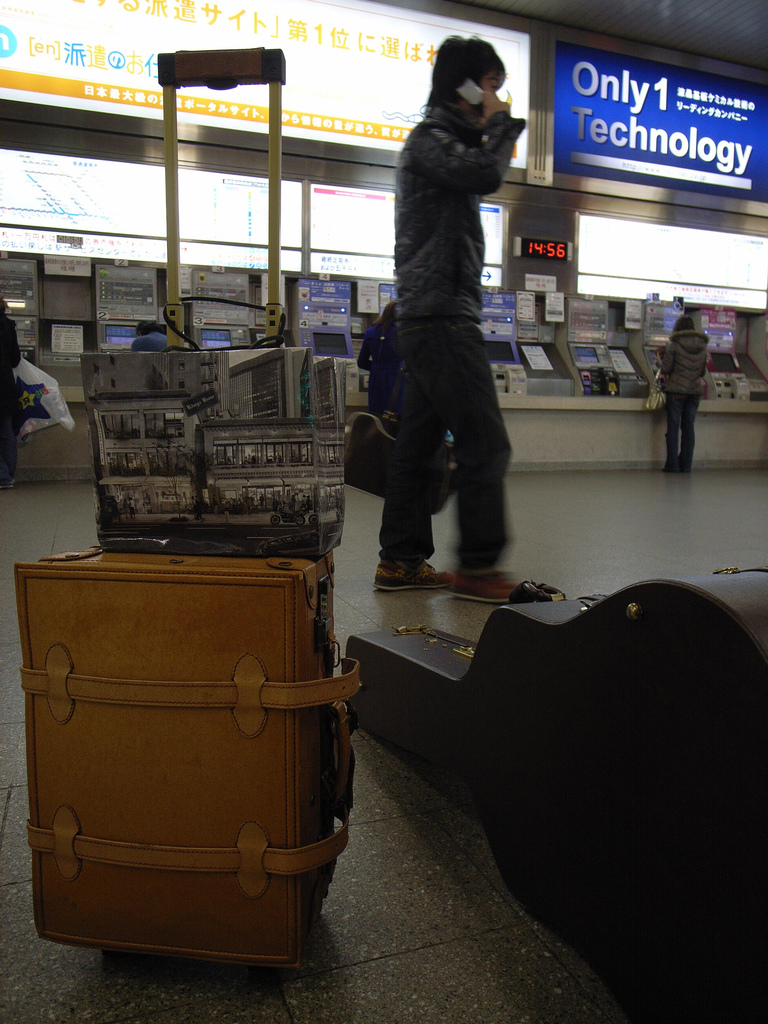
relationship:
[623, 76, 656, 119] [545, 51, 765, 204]
letter on sign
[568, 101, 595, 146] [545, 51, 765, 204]
letter on sign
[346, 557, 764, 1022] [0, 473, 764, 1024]
case on floor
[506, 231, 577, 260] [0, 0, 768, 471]
clock on wall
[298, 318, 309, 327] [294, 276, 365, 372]
number on kiosk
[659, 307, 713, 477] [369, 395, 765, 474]
person standing at counter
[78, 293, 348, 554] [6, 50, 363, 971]
bag on top of suitcase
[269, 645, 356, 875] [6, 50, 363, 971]
straps on suitcase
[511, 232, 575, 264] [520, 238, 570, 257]
clock with time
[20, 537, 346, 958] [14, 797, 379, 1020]
suitcase on floor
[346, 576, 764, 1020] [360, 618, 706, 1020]
case on floor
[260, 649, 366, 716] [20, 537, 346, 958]
strap on suitcase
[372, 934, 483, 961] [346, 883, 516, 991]
crack on floor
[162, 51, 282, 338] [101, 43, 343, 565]
handle on carrier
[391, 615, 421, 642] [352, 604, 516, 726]
clasp on case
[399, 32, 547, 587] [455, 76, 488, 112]
man talking on cellphone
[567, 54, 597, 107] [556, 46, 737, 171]
letter on sign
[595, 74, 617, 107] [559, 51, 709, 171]
letter on sign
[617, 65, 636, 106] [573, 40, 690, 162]
letter on sign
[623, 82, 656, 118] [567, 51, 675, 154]
letter on sign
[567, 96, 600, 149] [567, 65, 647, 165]
letter on sign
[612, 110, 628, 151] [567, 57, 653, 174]
letter on sign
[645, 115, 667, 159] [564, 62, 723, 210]
letter on sign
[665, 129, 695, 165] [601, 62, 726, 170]
letter on sign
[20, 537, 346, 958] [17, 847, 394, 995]
suitcase on ground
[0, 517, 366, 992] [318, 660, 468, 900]
suitcase on ground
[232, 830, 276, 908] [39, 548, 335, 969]
handle on suitcase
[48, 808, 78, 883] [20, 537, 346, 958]
handle on suitcase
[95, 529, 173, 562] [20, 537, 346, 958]
handle on suitcase